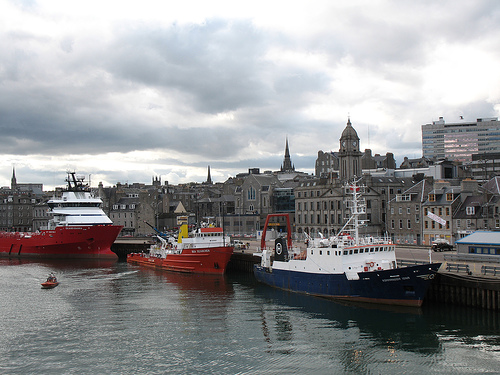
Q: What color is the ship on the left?
A: Red.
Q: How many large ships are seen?
A: Three.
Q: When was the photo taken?
A: Daytime.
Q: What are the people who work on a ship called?
A: Crew.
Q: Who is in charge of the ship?
A: Captain.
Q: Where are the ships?
A: Water.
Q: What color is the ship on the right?
A: Blue.